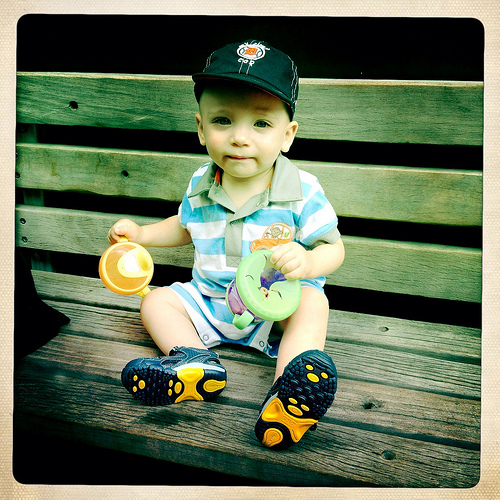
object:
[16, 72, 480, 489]
bench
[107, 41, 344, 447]
boy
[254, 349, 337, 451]
shoe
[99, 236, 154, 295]
sippy cup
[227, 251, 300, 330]
snack cup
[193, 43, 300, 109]
baseball cap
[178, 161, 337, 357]
onesie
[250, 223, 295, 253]
design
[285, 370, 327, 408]
tread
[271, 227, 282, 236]
monkey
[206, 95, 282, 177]
face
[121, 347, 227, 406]
shoe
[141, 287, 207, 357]
leg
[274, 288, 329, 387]
leg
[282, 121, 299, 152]
ear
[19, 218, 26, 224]
screws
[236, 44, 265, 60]
logo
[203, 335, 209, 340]
snap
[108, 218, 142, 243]
hand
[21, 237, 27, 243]
screws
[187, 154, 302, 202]
collar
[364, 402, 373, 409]
knot